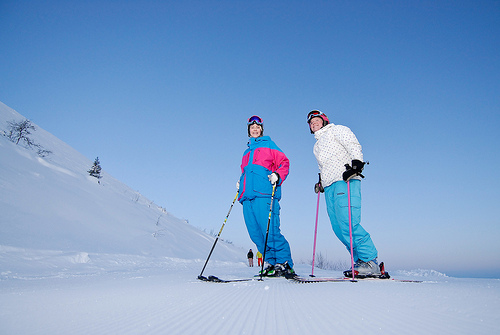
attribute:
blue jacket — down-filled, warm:
[237, 135, 290, 207]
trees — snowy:
[3, 117, 104, 180]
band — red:
[315, 114, 338, 126]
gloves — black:
[330, 159, 364, 172]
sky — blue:
[1, 0, 498, 278]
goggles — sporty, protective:
[305, 107, 320, 122]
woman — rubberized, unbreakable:
[291, 105, 401, 267]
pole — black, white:
[202, 183, 239, 278]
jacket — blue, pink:
[235, 134, 295, 194]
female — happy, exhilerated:
[231, 108, 299, 280]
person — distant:
[254, 249, 264, 267]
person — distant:
[242, 244, 256, 269]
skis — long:
[290, 263, 423, 289]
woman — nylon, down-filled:
[300, 102, 386, 282]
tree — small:
[87, 152, 105, 184]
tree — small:
[1, 113, 51, 164]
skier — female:
[186, 85, 303, 297]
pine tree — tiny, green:
[84, 152, 103, 184]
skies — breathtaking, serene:
[5, 7, 492, 277]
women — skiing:
[211, 107, 403, 282]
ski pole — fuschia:
[346, 179, 356, 277]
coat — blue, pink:
[232, 132, 288, 204]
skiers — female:
[131, 41, 396, 311]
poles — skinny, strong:
[334, 190, 358, 269]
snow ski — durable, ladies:
[198, 274, 255, 284]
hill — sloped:
[2, 103, 259, 276]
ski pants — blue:
[238, 196, 293, 266]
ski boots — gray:
[345, 257, 384, 278]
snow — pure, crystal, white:
[4, 104, 495, 332]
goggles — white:
[308, 109, 323, 119]